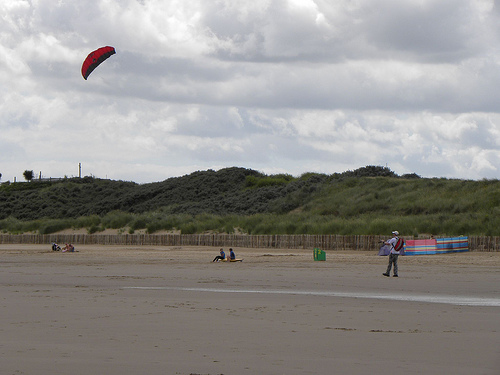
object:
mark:
[217, 305, 266, 318]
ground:
[0, 242, 499, 374]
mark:
[182, 346, 200, 355]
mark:
[210, 357, 223, 366]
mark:
[149, 340, 167, 352]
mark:
[198, 350, 210, 359]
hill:
[0, 165, 499, 250]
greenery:
[249, 211, 499, 236]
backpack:
[391, 237, 406, 252]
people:
[50, 242, 63, 251]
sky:
[0, 0, 499, 183]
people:
[210, 247, 227, 263]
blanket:
[216, 256, 243, 262]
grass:
[0, 210, 225, 235]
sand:
[1, 225, 185, 233]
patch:
[116, 285, 499, 307]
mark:
[319, 323, 357, 332]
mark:
[336, 305, 374, 319]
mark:
[428, 326, 459, 335]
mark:
[281, 326, 299, 334]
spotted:
[170, 298, 208, 314]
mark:
[368, 323, 395, 333]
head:
[391, 230, 399, 236]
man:
[379, 230, 404, 278]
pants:
[386, 253, 398, 274]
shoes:
[391, 273, 398, 277]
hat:
[390, 230, 399, 235]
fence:
[0, 232, 499, 252]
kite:
[81, 46, 116, 81]